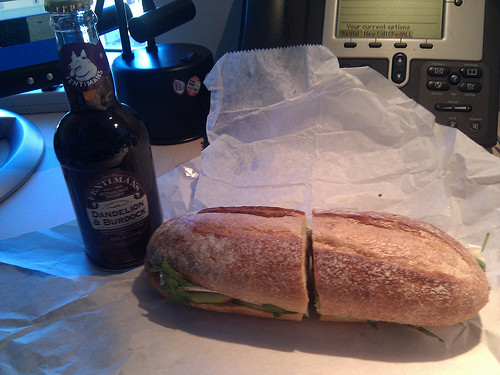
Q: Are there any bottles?
A: Yes, there is a bottle.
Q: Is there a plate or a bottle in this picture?
A: Yes, there is a bottle.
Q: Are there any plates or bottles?
A: Yes, there is a bottle.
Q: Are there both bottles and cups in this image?
A: No, there is a bottle but no cups.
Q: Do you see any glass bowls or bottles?
A: Yes, there is a glass bottle.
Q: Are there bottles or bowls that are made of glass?
A: Yes, the bottle is made of glass.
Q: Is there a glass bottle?
A: Yes, there is a bottle that is made of glass.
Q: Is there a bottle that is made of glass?
A: Yes, there is a bottle that is made of glass.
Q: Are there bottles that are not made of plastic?
A: Yes, there is a bottle that is made of glass.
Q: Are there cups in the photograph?
A: No, there are no cups.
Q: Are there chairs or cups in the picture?
A: No, there are no cups or chairs.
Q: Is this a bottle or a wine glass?
A: This is a bottle.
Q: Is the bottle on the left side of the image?
A: Yes, the bottle is on the left of the image.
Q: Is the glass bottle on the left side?
A: Yes, the bottle is on the left of the image.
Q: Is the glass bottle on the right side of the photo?
A: No, the bottle is on the left of the image.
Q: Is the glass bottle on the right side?
A: No, the bottle is on the left of the image.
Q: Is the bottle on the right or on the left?
A: The bottle is on the left of the image.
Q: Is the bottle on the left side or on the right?
A: The bottle is on the left of the image.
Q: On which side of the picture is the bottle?
A: The bottle is on the left of the image.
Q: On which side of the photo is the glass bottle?
A: The bottle is on the left of the image.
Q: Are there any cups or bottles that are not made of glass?
A: No, there is a bottle but it is made of glass.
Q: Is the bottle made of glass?
A: Yes, the bottle is made of glass.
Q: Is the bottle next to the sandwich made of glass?
A: Yes, the bottle is made of glass.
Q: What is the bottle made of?
A: The bottle is made of glass.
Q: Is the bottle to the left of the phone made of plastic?
A: No, the bottle is made of glass.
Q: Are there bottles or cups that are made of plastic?
A: No, there is a bottle but it is made of glass.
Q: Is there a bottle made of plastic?
A: No, there is a bottle but it is made of glass.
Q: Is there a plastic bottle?
A: No, there is a bottle but it is made of glass.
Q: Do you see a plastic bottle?
A: No, there is a bottle but it is made of glass.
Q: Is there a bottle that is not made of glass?
A: No, there is a bottle but it is made of glass.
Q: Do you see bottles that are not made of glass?
A: No, there is a bottle but it is made of glass.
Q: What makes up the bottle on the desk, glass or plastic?
A: The bottle is made of glass.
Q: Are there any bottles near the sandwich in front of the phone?
A: Yes, there is a bottle near the sandwich.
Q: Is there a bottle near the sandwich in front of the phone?
A: Yes, there is a bottle near the sandwich.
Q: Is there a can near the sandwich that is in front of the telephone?
A: No, there is a bottle near the sandwich.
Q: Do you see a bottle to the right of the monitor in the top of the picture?
A: Yes, there is a bottle to the right of the monitor.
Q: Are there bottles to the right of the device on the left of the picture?
A: Yes, there is a bottle to the right of the monitor.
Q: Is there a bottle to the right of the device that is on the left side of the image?
A: Yes, there is a bottle to the right of the monitor.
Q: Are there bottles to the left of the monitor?
A: No, the bottle is to the right of the monitor.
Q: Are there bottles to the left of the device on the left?
A: No, the bottle is to the right of the monitor.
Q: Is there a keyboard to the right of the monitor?
A: No, there is a bottle to the right of the monitor.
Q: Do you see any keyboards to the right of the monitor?
A: No, there is a bottle to the right of the monitor.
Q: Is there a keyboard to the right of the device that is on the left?
A: No, there is a bottle to the right of the monitor.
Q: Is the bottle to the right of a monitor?
A: Yes, the bottle is to the right of a monitor.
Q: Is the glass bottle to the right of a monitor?
A: Yes, the bottle is to the right of a monitor.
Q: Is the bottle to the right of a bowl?
A: No, the bottle is to the right of a monitor.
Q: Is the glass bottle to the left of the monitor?
A: No, the bottle is to the right of the monitor.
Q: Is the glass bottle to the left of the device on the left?
A: No, the bottle is to the right of the monitor.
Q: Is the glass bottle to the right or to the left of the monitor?
A: The bottle is to the right of the monitor.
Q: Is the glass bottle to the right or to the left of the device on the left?
A: The bottle is to the right of the monitor.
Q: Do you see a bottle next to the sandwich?
A: Yes, there is a bottle next to the sandwich.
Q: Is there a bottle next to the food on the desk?
A: Yes, there is a bottle next to the sandwich.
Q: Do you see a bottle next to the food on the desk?
A: Yes, there is a bottle next to the sandwich.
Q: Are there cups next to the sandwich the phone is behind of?
A: No, there is a bottle next to the sandwich.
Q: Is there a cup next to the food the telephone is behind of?
A: No, there is a bottle next to the sandwich.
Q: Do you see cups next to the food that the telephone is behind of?
A: No, there is a bottle next to the sandwich.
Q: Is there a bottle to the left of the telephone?
A: Yes, there is a bottle to the left of the telephone.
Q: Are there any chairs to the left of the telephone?
A: No, there is a bottle to the left of the telephone.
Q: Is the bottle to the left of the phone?
A: Yes, the bottle is to the left of the phone.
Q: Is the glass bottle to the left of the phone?
A: Yes, the bottle is to the left of the phone.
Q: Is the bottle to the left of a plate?
A: No, the bottle is to the left of the phone.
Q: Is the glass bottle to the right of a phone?
A: No, the bottle is to the left of a phone.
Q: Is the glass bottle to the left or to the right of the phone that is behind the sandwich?
A: The bottle is to the left of the phone.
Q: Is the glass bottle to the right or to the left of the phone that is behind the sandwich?
A: The bottle is to the left of the phone.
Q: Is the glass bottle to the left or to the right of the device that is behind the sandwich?
A: The bottle is to the left of the phone.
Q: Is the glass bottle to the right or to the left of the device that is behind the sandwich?
A: The bottle is to the left of the phone.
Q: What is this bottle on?
A: The bottle is on the desk.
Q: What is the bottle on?
A: The bottle is on the desk.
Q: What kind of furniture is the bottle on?
A: The bottle is on the desk.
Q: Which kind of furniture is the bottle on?
A: The bottle is on the desk.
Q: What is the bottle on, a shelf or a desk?
A: The bottle is on a desk.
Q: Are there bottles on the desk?
A: Yes, there is a bottle on the desk.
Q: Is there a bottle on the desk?
A: Yes, there is a bottle on the desk.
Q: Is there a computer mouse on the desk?
A: No, there is a bottle on the desk.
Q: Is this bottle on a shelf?
A: No, the bottle is on the desk.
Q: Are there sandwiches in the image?
A: Yes, there is a sandwich.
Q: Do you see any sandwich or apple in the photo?
A: Yes, there is a sandwich.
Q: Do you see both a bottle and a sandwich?
A: Yes, there are both a sandwich and a bottle.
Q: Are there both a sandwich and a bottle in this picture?
A: Yes, there are both a sandwich and a bottle.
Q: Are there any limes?
A: No, there are no limes.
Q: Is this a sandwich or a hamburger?
A: This is a sandwich.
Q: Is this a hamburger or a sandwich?
A: This is a sandwich.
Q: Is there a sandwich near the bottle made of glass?
A: Yes, there is a sandwich near the bottle.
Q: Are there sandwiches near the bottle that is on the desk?
A: Yes, there is a sandwich near the bottle.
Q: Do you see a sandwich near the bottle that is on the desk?
A: Yes, there is a sandwich near the bottle.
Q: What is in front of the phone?
A: The sandwich is in front of the phone.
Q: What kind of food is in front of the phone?
A: The food is a sandwich.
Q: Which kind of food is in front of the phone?
A: The food is a sandwich.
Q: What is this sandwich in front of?
A: The sandwich is in front of the telephone.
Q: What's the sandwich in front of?
A: The sandwich is in front of the telephone.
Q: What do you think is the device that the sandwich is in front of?
A: The device is a phone.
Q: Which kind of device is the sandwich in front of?
A: The sandwich is in front of the telephone.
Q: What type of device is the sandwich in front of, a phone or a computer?
A: The sandwich is in front of a phone.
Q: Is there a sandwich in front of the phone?
A: Yes, there is a sandwich in front of the phone.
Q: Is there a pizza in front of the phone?
A: No, there is a sandwich in front of the phone.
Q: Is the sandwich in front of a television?
A: No, the sandwich is in front of the telephone.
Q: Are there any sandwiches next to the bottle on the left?
A: Yes, there is a sandwich next to the bottle.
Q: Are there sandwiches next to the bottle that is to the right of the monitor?
A: Yes, there is a sandwich next to the bottle.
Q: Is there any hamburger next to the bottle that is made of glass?
A: No, there is a sandwich next to the bottle.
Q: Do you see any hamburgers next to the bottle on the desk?
A: No, there is a sandwich next to the bottle.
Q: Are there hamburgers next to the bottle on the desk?
A: No, there is a sandwich next to the bottle.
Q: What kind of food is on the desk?
A: The food is a sandwich.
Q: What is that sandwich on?
A: The sandwich is on the desk.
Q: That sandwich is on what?
A: The sandwich is on the desk.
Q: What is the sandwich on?
A: The sandwich is on the desk.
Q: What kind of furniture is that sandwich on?
A: The sandwich is on the desk.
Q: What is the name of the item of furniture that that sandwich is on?
A: The piece of furniture is a desk.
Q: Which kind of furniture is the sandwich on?
A: The sandwich is on the desk.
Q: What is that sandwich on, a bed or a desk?
A: The sandwich is on a desk.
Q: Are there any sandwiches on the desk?
A: Yes, there is a sandwich on the desk.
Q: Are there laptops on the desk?
A: No, there is a sandwich on the desk.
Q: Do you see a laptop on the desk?
A: No, there is a sandwich on the desk.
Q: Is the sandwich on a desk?
A: Yes, the sandwich is on a desk.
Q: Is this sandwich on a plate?
A: No, the sandwich is on a desk.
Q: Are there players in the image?
A: No, there are no players.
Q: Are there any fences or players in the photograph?
A: No, there are no players or fences.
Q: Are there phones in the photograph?
A: Yes, there is a phone.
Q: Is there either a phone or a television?
A: Yes, there is a phone.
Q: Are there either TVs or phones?
A: Yes, there is a phone.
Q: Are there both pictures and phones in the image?
A: No, there is a phone but no pictures.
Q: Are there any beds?
A: No, there are no beds.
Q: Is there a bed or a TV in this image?
A: No, there are no beds or televisions.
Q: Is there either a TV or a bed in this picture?
A: No, there are no beds or televisions.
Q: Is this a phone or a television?
A: This is a phone.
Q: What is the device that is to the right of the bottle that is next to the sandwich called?
A: The device is a phone.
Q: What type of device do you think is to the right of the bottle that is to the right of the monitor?
A: The device is a phone.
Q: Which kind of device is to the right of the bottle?
A: The device is a phone.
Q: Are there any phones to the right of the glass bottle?
A: Yes, there is a phone to the right of the bottle.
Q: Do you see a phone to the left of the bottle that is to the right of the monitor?
A: No, the phone is to the right of the bottle.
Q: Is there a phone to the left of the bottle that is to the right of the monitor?
A: No, the phone is to the right of the bottle.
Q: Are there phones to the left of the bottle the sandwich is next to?
A: No, the phone is to the right of the bottle.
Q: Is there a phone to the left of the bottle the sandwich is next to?
A: No, the phone is to the right of the bottle.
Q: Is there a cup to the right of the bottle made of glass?
A: No, there is a phone to the right of the bottle.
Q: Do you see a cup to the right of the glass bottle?
A: No, there is a phone to the right of the bottle.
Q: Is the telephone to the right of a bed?
A: No, the telephone is to the right of a bottle.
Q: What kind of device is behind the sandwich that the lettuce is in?
A: The device is a phone.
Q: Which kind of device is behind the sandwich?
A: The device is a phone.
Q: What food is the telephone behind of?
A: The telephone is behind the sandwich.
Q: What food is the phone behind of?
A: The telephone is behind the sandwich.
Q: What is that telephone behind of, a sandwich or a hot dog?
A: The telephone is behind a sandwich.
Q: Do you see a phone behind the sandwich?
A: Yes, there is a phone behind the sandwich.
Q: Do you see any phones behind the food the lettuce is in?
A: Yes, there is a phone behind the sandwich.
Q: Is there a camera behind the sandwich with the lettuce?
A: No, there is a phone behind the sandwich.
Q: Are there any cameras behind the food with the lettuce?
A: No, there is a phone behind the sandwich.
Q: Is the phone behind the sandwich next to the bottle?
A: Yes, the phone is behind the sandwich.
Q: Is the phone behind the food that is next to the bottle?
A: Yes, the phone is behind the sandwich.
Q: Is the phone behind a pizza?
A: No, the phone is behind the sandwich.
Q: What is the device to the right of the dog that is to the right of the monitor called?
A: The device is a phone.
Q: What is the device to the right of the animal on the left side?
A: The device is a phone.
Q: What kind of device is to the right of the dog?
A: The device is a phone.